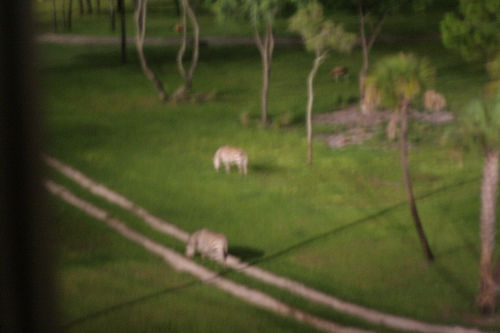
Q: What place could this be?
A: It is a field.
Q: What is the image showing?
A: It is showing a field.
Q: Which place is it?
A: It is a field.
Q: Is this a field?
A: Yes, it is a field.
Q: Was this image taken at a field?
A: Yes, it was taken in a field.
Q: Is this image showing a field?
A: Yes, it is showing a field.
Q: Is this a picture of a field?
A: Yes, it is showing a field.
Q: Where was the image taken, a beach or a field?
A: It was taken at a field.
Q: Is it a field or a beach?
A: It is a field.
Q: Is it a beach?
A: No, it is a field.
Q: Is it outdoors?
A: Yes, it is outdoors.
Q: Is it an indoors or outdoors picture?
A: It is outdoors.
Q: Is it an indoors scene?
A: No, it is outdoors.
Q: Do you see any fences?
A: No, there are no fences.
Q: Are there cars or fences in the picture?
A: No, there are no fences or cars.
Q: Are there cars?
A: No, there are no cars.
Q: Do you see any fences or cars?
A: No, there are no cars or fences.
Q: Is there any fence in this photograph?
A: No, there are no fences.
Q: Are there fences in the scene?
A: No, there are no fences.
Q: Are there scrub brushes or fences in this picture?
A: No, there are no fences or scrub brushes.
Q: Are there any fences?
A: No, there are no fences.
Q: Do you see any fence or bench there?
A: No, there are no fences or benches.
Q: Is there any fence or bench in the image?
A: No, there are no fences or benches.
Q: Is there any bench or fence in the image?
A: No, there are no fences or benches.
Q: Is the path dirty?
A: Yes, the path is dirty.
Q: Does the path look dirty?
A: Yes, the path is dirty.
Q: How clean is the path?
A: The path is dirty.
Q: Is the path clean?
A: No, the path is dirty.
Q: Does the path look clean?
A: No, the path is dirty.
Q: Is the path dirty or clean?
A: The path is dirty.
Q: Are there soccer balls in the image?
A: No, there are no soccer balls.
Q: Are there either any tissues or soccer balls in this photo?
A: No, there are no soccer balls or tissues.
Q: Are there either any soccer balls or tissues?
A: No, there are no soccer balls or tissues.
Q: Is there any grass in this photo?
A: Yes, there is grass.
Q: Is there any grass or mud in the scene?
A: Yes, there is grass.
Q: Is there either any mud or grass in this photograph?
A: Yes, there is grass.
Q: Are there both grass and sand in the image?
A: No, there is grass but no sand.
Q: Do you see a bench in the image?
A: No, there are no benches.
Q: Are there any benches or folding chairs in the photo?
A: No, there are no benches or folding chairs.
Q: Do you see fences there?
A: No, there are no fences.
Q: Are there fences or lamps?
A: No, there are no fences or lamps.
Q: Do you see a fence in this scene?
A: No, there are no fences.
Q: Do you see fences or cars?
A: No, there are no fences or cars.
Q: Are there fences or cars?
A: No, there are no fences or cars.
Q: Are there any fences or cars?
A: No, there are no cars or fences.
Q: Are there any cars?
A: No, there are no cars.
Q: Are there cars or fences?
A: No, there are no cars or fences.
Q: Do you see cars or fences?
A: No, there are no cars or fences.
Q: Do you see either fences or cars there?
A: No, there are no cars or fences.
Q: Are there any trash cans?
A: No, there are no trash cans.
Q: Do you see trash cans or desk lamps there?
A: No, there are no trash cans or desk lamps.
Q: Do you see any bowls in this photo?
A: No, there are no bowls.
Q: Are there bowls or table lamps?
A: No, there are no bowls or table lamps.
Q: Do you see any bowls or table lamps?
A: No, there are no bowls or table lamps.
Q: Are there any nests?
A: No, there are no nests.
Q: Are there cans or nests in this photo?
A: No, there are no nests or cans.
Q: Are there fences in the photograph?
A: No, there are no fences.